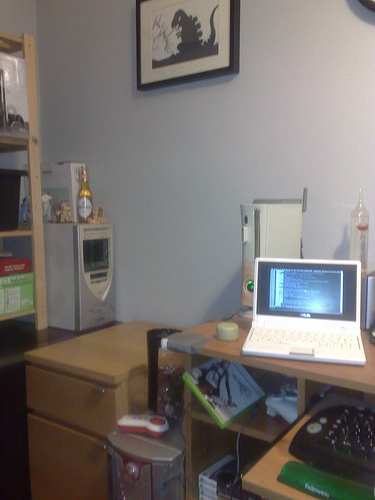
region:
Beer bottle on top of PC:
[75, 162, 92, 218]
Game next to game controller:
[181, 356, 267, 428]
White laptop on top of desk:
[241, 256, 366, 364]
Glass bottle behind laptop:
[344, 186, 368, 272]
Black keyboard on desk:
[288, 399, 373, 480]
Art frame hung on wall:
[133, 0, 236, 93]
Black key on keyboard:
[336, 439, 351, 454]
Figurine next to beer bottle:
[56, 196, 73, 221]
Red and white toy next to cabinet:
[118, 412, 169, 437]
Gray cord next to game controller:
[219, 400, 263, 499]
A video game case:
[178, 352, 264, 420]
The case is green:
[174, 365, 253, 419]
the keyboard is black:
[287, 396, 371, 492]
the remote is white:
[104, 402, 179, 436]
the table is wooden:
[4, 321, 139, 467]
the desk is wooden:
[175, 280, 374, 465]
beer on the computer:
[65, 153, 89, 230]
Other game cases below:
[197, 425, 244, 497]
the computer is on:
[241, 260, 356, 308]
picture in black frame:
[135, 0, 241, 91]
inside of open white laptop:
[242, 257, 364, 365]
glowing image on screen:
[266, 266, 345, 315]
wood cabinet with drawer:
[29, 319, 184, 498]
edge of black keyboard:
[288, 402, 374, 478]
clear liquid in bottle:
[349, 185, 369, 272]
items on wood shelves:
[1, 33, 47, 331]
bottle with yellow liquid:
[77, 166, 93, 223]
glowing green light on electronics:
[239, 199, 306, 315]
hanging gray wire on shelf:
[229, 408, 260, 482]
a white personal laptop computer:
[236, 252, 364, 369]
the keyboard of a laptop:
[261, 318, 343, 345]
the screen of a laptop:
[262, 265, 352, 315]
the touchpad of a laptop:
[281, 340, 306, 348]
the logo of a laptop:
[293, 307, 314, 320]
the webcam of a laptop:
[294, 256, 317, 263]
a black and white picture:
[121, 11, 238, 82]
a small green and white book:
[182, 363, 253, 423]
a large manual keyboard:
[315, 403, 372, 473]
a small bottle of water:
[347, 193, 373, 258]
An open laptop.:
[240, 251, 366, 366]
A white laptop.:
[242, 256, 366, 366]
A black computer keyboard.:
[286, 401, 372, 487]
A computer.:
[42, 221, 118, 334]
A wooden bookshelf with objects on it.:
[0, 27, 50, 332]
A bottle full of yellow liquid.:
[76, 162, 95, 221]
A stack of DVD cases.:
[197, 453, 248, 499]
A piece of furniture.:
[22, 320, 190, 499]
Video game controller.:
[263, 379, 299, 424]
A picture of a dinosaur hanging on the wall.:
[135, 2, 241, 88]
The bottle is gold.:
[70, 159, 98, 224]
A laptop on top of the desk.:
[247, 263, 367, 365]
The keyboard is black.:
[308, 395, 374, 458]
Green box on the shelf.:
[3, 260, 40, 316]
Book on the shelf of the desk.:
[192, 363, 254, 417]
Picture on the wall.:
[112, 2, 245, 95]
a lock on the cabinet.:
[87, 373, 105, 398]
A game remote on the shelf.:
[257, 382, 306, 416]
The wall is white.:
[104, 107, 320, 194]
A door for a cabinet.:
[25, 414, 110, 499]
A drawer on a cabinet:
[24, 363, 120, 438]